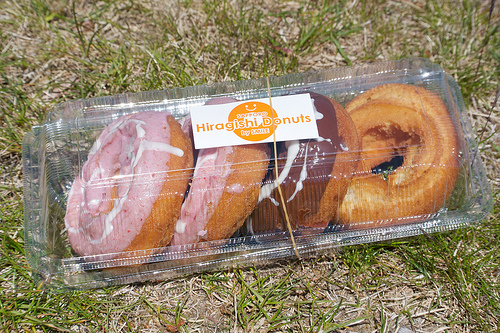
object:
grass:
[0, 0, 500, 333]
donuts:
[63, 82, 458, 272]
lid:
[21, 57, 492, 289]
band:
[261, 141, 283, 188]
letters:
[196, 114, 311, 133]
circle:
[228, 101, 279, 141]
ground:
[0, 0, 500, 333]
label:
[190, 92, 320, 150]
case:
[21, 58, 491, 290]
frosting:
[239, 91, 339, 239]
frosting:
[64, 118, 183, 245]